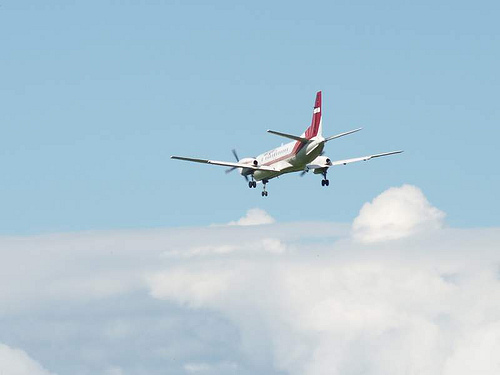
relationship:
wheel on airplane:
[261, 191, 265, 196] [169, 90, 403, 196]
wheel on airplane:
[322, 180, 325, 186] [169, 90, 403, 196]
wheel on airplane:
[238, 180, 268, 196] [147, 77, 423, 216]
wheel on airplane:
[318, 171, 330, 189] [147, 77, 423, 216]